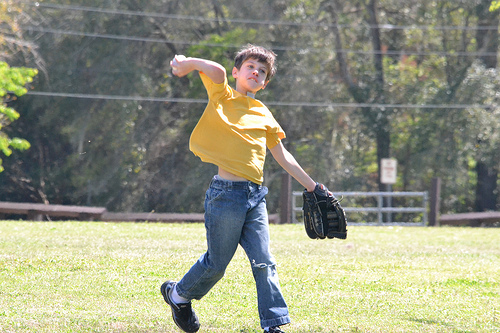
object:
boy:
[165, 43, 349, 332]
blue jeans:
[176, 175, 291, 327]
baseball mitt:
[298, 186, 349, 241]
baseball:
[169, 55, 187, 78]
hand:
[166, 52, 195, 75]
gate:
[291, 186, 434, 230]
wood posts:
[277, 155, 449, 229]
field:
[0, 220, 497, 331]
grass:
[2, 218, 498, 331]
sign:
[381, 158, 398, 185]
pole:
[384, 182, 392, 225]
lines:
[0, 2, 500, 113]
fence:
[2, 193, 498, 230]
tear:
[253, 258, 276, 275]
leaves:
[0, 57, 39, 161]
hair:
[232, 44, 278, 82]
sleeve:
[198, 70, 234, 99]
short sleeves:
[186, 69, 287, 187]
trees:
[1, 0, 497, 224]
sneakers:
[160, 278, 202, 333]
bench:
[0, 201, 106, 223]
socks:
[171, 284, 192, 305]